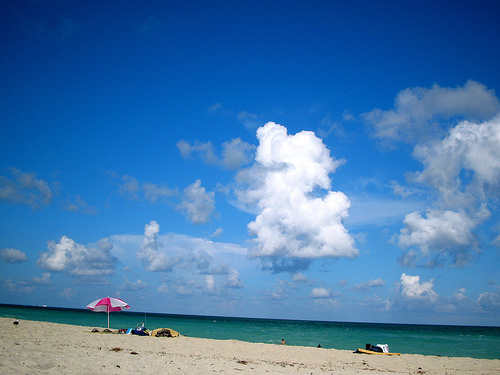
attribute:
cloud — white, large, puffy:
[235, 113, 357, 269]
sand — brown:
[2, 315, 499, 369]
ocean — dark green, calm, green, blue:
[8, 306, 500, 361]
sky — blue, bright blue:
[4, 3, 500, 316]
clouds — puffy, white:
[4, 70, 500, 318]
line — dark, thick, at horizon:
[3, 298, 499, 329]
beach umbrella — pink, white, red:
[92, 294, 130, 327]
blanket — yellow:
[154, 324, 181, 337]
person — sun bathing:
[122, 324, 146, 336]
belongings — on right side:
[350, 335, 396, 359]